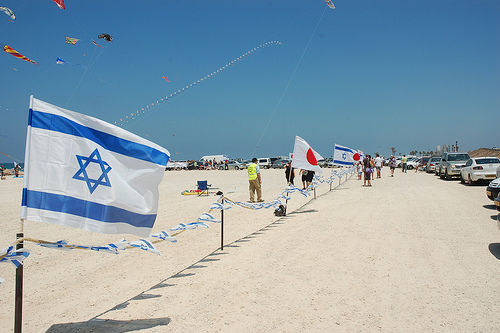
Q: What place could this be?
A: It is a beach.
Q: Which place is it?
A: It is a beach.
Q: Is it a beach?
A: Yes, it is a beach.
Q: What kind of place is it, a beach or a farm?
A: It is a beach.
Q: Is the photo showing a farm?
A: No, the picture is showing a beach.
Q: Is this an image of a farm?
A: No, the picture is showing a beach.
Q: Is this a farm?
A: No, it is a beach.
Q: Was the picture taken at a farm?
A: No, the picture was taken in a beach.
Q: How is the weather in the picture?
A: It is clear.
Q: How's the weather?
A: It is clear.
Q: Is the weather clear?
A: Yes, it is clear.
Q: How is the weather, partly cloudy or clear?
A: It is clear.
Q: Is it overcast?
A: No, it is clear.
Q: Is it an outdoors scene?
A: Yes, it is outdoors.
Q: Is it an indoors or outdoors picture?
A: It is outdoors.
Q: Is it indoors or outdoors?
A: It is outdoors.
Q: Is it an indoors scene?
A: No, it is outdoors.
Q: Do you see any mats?
A: No, there are no mats.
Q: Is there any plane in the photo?
A: No, there are no airplanes.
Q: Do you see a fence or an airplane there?
A: No, there are no airplanes or fences.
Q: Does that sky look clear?
A: Yes, the sky is clear.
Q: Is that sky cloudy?
A: No, the sky is clear.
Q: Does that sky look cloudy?
A: No, the sky is clear.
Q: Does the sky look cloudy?
A: No, the sky is clear.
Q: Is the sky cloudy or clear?
A: The sky is clear.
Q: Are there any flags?
A: Yes, there is a flag.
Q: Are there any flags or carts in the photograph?
A: Yes, there is a flag.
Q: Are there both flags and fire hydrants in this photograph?
A: No, there is a flag but no fire hydrants.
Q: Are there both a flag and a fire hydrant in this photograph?
A: No, there is a flag but no fire hydrants.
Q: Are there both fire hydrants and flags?
A: No, there is a flag but no fire hydrants.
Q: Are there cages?
A: No, there are no cages.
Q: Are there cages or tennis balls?
A: No, there are no cages or tennis balls.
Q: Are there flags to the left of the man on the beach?
A: Yes, there is a flag to the left of the man.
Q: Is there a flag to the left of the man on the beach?
A: Yes, there is a flag to the left of the man.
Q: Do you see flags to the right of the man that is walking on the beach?
A: No, the flag is to the left of the man.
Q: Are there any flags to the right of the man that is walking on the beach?
A: No, the flag is to the left of the man.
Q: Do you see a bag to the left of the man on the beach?
A: No, there is a flag to the left of the man.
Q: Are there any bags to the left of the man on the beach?
A: No, there is a flag to the left of the man.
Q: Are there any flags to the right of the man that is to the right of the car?
A: Yes, there is a flag to the right of the man.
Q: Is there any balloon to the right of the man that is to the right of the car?
A: No, there is a flag to the right of the man.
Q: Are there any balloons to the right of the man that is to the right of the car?
A: No, there is a flag to the right of the man.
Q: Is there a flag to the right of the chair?
A: Yes, there is a flag to the right of the chair.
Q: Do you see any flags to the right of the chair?
A: Yes, there is a flag to the right of the chair.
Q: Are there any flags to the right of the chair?
A: Yes, there is a flag to the right of the chair.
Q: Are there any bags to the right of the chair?
A: No, there is a flag to the right of the chair.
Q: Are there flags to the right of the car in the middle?
A: Yes, there is a flag to the right of the car.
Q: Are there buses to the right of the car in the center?
A: No, there is a flag to the right of the car.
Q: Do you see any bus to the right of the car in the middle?
A: No, there is a flag to the right of the car.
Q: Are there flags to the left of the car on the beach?
A: Yes, there is a flag to the left of the car.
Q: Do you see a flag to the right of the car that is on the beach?
A: No, the flag is to the left of the car.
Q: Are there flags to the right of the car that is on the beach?
A: No, the flag is to the left of the car.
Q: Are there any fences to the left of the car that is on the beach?
A: No, there is a flag to the left of the car.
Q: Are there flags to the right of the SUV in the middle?
A: Yes, there is a flag to the right of the SUV.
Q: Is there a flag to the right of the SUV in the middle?
A: Yes, there is a flag to the right of the SUV.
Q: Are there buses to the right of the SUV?
A: No, there is a flag to the right of the SUV.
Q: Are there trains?
A: No, there are no trains.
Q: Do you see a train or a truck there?
A: No, there are no trains or trucks.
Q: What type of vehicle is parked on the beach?
A: The vehicle is a car.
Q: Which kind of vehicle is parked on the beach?
A: The vehicle is a car.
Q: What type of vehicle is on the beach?
A: The vehicle is a car.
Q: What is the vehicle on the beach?
A: The vehicle is a car.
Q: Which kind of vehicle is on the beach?
A: The vehicle is a car.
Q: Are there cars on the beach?
A: Yes, there is a car on the beach.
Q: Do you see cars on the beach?
A: Yes, there is a car on the beach.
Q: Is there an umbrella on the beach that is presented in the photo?
A: No, there is a car on the beach.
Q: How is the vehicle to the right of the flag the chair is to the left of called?
A: The vehicle is a car.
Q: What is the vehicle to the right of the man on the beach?
A: The vehicle is a car.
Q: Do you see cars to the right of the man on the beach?
A: Yes, there is a car to the right of the man.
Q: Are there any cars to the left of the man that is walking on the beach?
A: No, the car is to the right of the man.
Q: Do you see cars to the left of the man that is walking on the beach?
A: No, the car is to the right of the man.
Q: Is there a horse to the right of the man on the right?
A: No, there is a car to the right of the man.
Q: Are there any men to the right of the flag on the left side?
A: Yes, there is a man to the right of the flag.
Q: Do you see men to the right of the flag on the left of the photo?
A: Yes, there is a man to the right of the flag.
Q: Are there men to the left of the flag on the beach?
A: No, the man is to the right of the flag.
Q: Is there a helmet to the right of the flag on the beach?
A: No, there is a man to the right of the flag.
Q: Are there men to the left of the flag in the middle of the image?
A: Yes, there is a man to the left of the flag.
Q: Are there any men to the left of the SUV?
A: No, the man is to the right of the SUV.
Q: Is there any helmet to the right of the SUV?
A: No, there is a man to the right of the SUV.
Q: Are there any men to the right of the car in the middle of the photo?
A: Yes, there is a man to the right of the car.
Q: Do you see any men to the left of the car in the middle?
A: No, the man is to the right of the car.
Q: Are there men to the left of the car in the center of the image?
A: No, the man is to the right of the car.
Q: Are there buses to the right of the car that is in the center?
A: No, there is a man to the right of the car.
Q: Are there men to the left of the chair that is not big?
A: No, the man is to the right of the chair.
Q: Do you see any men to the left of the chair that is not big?
A: No, the man is to the right of the chair.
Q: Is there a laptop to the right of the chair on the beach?
A: No, there is a man to the right of the chair.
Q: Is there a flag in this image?
A: Yes, there is a flag.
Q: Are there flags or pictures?
A: Yes, there is a flag.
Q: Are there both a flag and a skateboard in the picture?
A: No, there is a flag but no skateboards.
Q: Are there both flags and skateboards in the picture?
A: No, there is a flag but no skateboards.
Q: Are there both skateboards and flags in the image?
A: No, there is a flag but no skateboards.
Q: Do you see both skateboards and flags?
A: No, there is a flag but no skateboards.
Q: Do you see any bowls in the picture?
A: No, there are no bowls.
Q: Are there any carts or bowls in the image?
A: No, there are no bowls or carts.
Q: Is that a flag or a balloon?
A: That is a flag.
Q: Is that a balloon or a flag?
A: That is a flag.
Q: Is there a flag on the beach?
A: Yes, there is a flag on the beach.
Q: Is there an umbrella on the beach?
A: No, there is a flag on the beach.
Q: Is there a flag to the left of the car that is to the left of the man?
A: Yes, there is a flag to the left of the car.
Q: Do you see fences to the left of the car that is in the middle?
A: No, there is a flag to the left of the car.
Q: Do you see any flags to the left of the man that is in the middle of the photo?
A: Yes, there is a flag to the left of the man.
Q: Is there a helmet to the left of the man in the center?
A: No, there is a flag to the left of the man.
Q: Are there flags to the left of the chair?
A: Yes, there is a flag to the left of the chair.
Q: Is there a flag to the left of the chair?
A: Yes, there is a flag to the left of the chair.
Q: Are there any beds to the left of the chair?
A: No, there is a flag to the left of the chair.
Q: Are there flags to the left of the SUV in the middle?
A: Yes, there is a flag to the left of the SUV.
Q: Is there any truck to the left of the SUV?
A: No, there is a flag to the left of the SUV.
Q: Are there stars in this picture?
A: Yes, there is a star.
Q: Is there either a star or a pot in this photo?
A: Yes, there is a star.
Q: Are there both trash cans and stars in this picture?
A: No, there is a star but no trash cans.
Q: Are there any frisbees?
A: No, there are no frisbees.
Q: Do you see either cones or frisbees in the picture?
A: No, there are no frisbees or cones.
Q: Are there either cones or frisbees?
A: No, there are no frisbees or cones.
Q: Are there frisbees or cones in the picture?
A: No, there are no frisbees or cones.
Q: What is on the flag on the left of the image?
A: The star is on the flag.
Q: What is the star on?
A: The star is on the flag.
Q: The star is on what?
A: The star is on the flag.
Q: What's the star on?
A: The star is on the flag.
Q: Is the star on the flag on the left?
A: Yes, the star is on the flag.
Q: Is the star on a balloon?
A: No, the star is on the flag.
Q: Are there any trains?
A: No, there are no trains.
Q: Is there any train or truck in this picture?
A: No, there are no trains or trucks.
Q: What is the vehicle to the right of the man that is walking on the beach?
A: The vehicle is a car.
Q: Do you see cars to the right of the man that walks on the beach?
A: Yes, there is a car to the right of the man.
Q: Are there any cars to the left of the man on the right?
A: No, the car is to the right of the man.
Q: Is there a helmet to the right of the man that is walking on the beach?
A: No, there is a car to the right of the man.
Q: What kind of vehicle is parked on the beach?
A: The vehicle is a car.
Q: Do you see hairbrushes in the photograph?
A: No, there are no hairbrushes.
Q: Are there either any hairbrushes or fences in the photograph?
A: No, there are no hairbrushes or fences.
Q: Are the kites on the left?
A: Yes, the kites are on the left of the image.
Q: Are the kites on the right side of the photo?
A: No, the kites are on the left of the image.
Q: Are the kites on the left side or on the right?
A: The kites are on the left of the image.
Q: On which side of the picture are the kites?
A: The kites are on the left of the image.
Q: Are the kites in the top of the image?
A: Yes, the kites are in the top of the image.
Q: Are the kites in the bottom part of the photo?
A: No, the kites are in the top of the image.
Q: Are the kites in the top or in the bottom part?
A: The kites are in the top of the image.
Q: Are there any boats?
A: No, there are no boats.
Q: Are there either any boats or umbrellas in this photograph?
A: No, there are no boats or umbrellas.